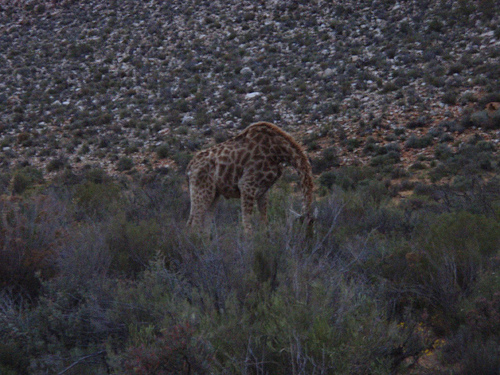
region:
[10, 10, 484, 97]
Rocky landscape in the background.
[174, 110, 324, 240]
Giraffe eating the grass.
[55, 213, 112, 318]
Gray colored weeds growing in grass.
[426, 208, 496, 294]
Green bushes in the grass.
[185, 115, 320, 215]
Brown orange spots on giraffee.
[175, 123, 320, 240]
Four legs on giraffe.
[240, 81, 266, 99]
Light gray rock in background.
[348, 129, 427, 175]
Brown dirt in landscape.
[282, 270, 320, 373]
Gray branches in the forefront.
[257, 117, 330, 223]
Orange brown mane on giraffe.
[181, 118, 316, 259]
giraffe standing in low light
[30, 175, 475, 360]
shrubbery in front of giraffe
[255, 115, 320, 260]
neck deeply bent in front of body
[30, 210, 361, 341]
silvery purple flowers along branches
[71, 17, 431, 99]
dots of greenery on rocky and steep slope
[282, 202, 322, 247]
pointy grey ears on top of head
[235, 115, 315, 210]
curve of brown mane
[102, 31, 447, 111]
gray stones between bushes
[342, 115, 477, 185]
exposed brown dirt between bushes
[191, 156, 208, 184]
bump on rear hip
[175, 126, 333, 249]
Giraffe in the field.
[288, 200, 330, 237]
The head is down.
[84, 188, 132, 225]
The grass is green.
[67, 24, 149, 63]
Gravel on the side of the hill.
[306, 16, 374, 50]
Grass in the gravel.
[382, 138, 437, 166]
Dirt on the ground.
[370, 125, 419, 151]
Gravel in the dirt.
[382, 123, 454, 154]
Grass in the dirt.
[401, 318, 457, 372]
Flowers in the dirt.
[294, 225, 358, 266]
The twigs are grey.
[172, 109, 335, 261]
Giraffe in the grass.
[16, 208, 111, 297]
Twigs in the grass.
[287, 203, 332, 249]
The giraffe is eating.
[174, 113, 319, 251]
Giraffe is leaning over.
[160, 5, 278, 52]
Gravel on the ground.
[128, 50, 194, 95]
Small grass patches in the grass.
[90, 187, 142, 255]
The grass is green.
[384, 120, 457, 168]
Dirt on the ground.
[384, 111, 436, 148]
Gravel on the dirt.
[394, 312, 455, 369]
Small dirt patch in the grass.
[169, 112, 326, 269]
giraffe standing in grass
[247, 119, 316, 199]
mane on giraffe's neck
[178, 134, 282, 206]
spots on giraffe's body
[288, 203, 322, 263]
giraffe's head grazing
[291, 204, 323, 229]
ears of the giraffe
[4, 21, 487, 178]
hillside covered in tufts of frass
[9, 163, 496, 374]
grasses the giraffe is grazing in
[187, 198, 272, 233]
speckled legs of giraffe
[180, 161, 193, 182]
tail of giraffe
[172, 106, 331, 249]
giraffe with neck bent